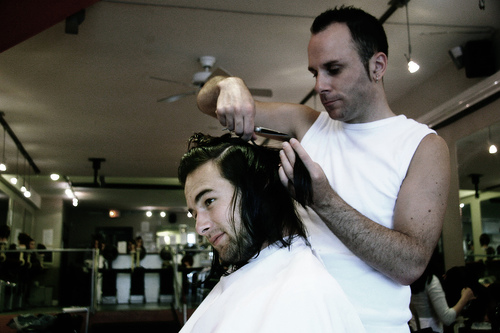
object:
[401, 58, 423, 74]
ceiling light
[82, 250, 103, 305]
hair dryer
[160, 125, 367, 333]
man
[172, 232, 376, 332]
apron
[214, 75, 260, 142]
hand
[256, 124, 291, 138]
comb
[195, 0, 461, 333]
barber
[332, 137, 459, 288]
hairy arm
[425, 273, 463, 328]
arm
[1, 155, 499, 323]
background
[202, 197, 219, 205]
eye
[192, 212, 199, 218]
eye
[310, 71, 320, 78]
eye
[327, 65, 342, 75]
eye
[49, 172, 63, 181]
lights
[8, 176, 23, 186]
lights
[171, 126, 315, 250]
hair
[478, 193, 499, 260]
mirror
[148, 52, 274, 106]
fan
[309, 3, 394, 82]
hair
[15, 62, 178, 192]
ceiling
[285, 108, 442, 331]
shirt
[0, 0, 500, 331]
hair salon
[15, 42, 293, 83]
background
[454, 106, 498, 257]
wall